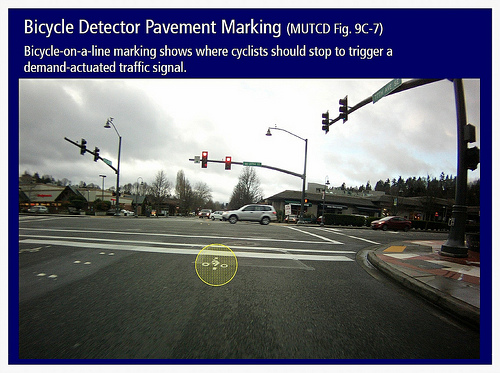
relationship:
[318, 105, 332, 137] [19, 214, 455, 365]
traffic light on side of road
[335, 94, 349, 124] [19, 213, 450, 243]
traffic light hanging above road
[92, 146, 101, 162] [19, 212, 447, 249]
traffic light hanging above road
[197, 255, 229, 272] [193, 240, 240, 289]
cyclist appearing in circle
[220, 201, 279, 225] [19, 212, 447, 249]
vehicle crossing road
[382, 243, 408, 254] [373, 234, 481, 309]
spot painted on sidewalk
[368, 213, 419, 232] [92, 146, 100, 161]
vehicle waiting at traffic light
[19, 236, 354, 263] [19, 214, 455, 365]
marking painted on road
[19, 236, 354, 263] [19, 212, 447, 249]
marking painted on road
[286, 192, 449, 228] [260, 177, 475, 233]
wall on side of a building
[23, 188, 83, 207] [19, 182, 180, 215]
wall on side of a building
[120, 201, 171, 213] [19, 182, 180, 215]
wall on side of a building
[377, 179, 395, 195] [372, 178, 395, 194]
leaves on tree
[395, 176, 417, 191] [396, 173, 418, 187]
leaves on tree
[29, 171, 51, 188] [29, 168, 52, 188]
leaves on tree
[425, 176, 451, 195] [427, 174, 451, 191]
leaves on tree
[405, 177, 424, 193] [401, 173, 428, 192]
leaves on tree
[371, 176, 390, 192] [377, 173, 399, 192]
leaves on tree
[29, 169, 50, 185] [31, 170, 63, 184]
leaves on tree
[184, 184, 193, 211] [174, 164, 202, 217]
leaves on tree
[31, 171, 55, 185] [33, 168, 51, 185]
leaves on tree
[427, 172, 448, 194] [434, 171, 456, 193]
leaves on tree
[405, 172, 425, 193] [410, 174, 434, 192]
leaves on tree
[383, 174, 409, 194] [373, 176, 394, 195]
leaves on tree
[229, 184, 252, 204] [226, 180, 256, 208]
leaves on tree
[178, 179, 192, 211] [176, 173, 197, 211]
leaves on tree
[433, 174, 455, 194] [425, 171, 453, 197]
leaves on tree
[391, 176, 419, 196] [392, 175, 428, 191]
leaves on tree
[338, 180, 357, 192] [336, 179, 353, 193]
leaves on tree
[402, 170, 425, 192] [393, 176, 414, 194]
leaves on tree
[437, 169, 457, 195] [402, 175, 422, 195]
leaves on tree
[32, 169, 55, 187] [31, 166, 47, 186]
leaves on tree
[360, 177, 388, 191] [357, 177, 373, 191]
leaves on tree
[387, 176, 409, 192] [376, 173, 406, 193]
leaves on tree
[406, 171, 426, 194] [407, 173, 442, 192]
leaves on tree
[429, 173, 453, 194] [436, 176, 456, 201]
leaves on tree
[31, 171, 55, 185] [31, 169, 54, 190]
leaves on tree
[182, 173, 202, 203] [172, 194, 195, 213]
leaves on tree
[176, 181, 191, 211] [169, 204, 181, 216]
leaves on tree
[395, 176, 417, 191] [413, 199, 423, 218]
leaves on tree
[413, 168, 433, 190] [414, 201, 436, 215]
leaves on tree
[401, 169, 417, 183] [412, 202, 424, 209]
leaves on tree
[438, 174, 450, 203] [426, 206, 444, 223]
leaves on tree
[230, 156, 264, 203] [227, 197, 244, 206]
leaves on tree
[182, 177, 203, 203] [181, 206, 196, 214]
leaves on tree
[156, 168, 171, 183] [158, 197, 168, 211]
leaves on tree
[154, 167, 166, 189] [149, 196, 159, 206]
leaves on tree